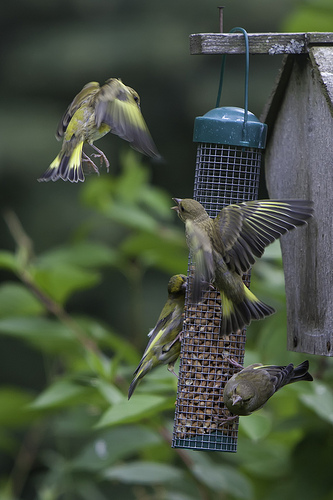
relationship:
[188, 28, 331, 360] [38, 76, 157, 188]
birdhouse besides bird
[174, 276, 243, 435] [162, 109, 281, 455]
seeds are inside feeder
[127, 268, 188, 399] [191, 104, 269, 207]
bird pecking through feeder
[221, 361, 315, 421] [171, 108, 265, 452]
bird on bird feeder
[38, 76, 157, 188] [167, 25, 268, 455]
bird perched on feeder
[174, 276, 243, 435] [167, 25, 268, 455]
seeds in feeder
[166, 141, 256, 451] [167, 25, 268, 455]
wire wrapped around feeder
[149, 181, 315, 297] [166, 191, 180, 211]
bird opens mouth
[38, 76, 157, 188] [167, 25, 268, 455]
bird around a feeder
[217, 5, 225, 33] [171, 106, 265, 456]
nail around a feeder